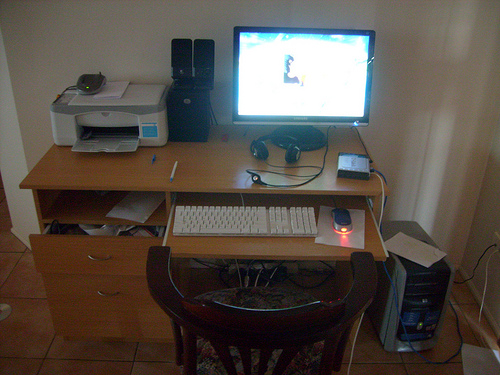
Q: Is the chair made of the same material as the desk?
A: Yes, both the chair and the desk are made of wood.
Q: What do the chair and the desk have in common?
A: The material, both the chair and the desk are wooden.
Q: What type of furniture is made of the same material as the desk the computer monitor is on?
A: The chair is made of the same material as the desk.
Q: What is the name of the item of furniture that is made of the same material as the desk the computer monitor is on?
A: The piece of furniture is a chair.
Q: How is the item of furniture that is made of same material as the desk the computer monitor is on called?
A: The piece of furniture is a chair.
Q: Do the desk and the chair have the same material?
A: Yes, both the desk and the chair are made of wood.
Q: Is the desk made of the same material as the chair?
A: Yes, both the desk and the chair are made of wood.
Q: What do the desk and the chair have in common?
A: The material, both the desk and the chair are wooden.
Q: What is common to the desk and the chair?
A: The material, both the desk and the chair are wooden.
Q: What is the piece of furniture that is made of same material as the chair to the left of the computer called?
A: The piece of furniture is a desk.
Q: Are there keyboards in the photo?
A: Yes, there is a keyboard.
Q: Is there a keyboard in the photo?
A: Yes, there is a keyboard.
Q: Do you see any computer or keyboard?
A: Yes, there is a keyboard.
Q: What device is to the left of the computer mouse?
A: The device is a keyboard.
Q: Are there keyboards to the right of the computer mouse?
A: No, the keyboard is to the left of the computer mouse.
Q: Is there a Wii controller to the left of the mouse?
A: No, there is a keyboard to the left of the mouse.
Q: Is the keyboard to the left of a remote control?
A: No, the keyboard is to the left of the computer mouse.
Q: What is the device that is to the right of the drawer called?
A: The device is a keyboard.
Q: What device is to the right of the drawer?
A: The device is a keyboard.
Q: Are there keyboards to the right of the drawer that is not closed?
A: Yes, there is a keyboard to the right of the drawer.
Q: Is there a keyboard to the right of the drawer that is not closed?
A: Yes, there is a keyboard to the right of the drawer.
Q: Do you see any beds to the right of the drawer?
A: No, there is a keyboard to the right of the drawer.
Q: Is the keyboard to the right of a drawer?
A: Yes, the keyboard is to the right of a drawer.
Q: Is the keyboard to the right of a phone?
A: No, the keyboard is to the right of a drawer.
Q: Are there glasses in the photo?
A: No, there are no glasses.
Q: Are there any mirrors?
A: No, there are no mirrors.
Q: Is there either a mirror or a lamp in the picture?
A: No, there are no mirrors or lamps.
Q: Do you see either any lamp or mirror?
A: No, there are no mirrors or lamps.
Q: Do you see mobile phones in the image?
A: No, there are no mobile phones.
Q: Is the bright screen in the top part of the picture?
A: Yes, the screen is in the top of the image.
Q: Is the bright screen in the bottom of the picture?
A: No, the screen is in the top of the image.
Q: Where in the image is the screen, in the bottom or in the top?
A: The screen is in the top of the image.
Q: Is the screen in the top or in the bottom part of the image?
A: The screen is in the top of the image.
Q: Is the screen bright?
A: Yes, the screen is bright.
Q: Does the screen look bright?
A: Yes, the screen is bright.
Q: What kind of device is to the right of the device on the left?
A: The device is a screen.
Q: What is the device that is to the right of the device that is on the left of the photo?
A: The device is a screen.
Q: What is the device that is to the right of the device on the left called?
A: The device is a screen.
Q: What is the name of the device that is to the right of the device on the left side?
A: The device is a screen.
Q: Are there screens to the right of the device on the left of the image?
A: Yes, there is a screen to the right of the printer.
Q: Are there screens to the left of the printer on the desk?
A: No, the screen is to the right of the printer.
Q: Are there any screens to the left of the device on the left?
A: No, the screen is to the right of the printer.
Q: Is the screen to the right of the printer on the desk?
A: Yes, the screen is to the right of the printer.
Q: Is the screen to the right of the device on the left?
A: Yes, the screen is to the right of the printer.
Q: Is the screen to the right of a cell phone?
A: No, the screen is to the right of the printer.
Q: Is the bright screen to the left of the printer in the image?
A: No, the screen is to the right of the printer.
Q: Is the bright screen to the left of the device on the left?
A: No, the screen is to the right of the printer.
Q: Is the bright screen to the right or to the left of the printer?
A: The screen is to the right of the printer.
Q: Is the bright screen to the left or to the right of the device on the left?
A: The screen is to the right of the printer.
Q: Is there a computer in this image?
A: Yes, there is a computer.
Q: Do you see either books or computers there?
A: Yes, there is a computer.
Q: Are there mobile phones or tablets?
A: No, there are no mobile phones or tablets.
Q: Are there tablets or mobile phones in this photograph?
A: No, there are no mobile phones or tablets.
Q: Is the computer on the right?
A: Yes, the computer is on the right of the image.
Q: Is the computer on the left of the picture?
A: No, the computer is on the right of the image.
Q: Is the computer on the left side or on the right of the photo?
A: The computer is on the right of the image.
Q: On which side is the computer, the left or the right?
A: The computer is on the right of the image.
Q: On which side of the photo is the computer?
A: The computer is on the right of the image.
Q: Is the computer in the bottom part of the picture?
A: Yes, the computer is in the bottom of the image.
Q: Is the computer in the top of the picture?
A: No, the computer is in the bottom of the image.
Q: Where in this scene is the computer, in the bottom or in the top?
A: The computer is in the bottom of the image.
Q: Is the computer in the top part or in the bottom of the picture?
A: The computer is in the bottom of the image.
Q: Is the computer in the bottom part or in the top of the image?
A: The computer is in the bottom of the image.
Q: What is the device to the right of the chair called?
A: The device is a computer.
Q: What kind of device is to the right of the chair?
A: The device is a computer.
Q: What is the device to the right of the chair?
A: The device is a computer.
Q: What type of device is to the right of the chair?
A: The device is a computer.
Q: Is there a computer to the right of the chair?
A: Yes, there is a computer to the right of the chair.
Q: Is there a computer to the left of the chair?
A: No, the computer is to the right of the chair.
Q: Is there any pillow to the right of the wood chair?
A: No, there is a computer to the right of the chair.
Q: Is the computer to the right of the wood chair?
A: Yes, the computer is to the right of the chair.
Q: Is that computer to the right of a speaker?
A: No, the computer is to the right of the chair.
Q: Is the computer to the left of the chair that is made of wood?
A: No, the computer is to the right of the chair.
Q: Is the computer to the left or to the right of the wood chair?
A: The computer is to the right of the chair.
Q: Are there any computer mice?
A: Yes, there is a computer mouse.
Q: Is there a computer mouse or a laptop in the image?
A: Yes, there is a computer mouse.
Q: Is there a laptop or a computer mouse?
A: Yes, there is a computer mouse.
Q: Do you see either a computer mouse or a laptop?
A: Yes, there is a computer mouse.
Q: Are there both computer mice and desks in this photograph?
A: Yes, there are both a computer mouse and a desk.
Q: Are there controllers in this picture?
A: No, there are no controllers.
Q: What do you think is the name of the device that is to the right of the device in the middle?
A: The device is a computer mouse.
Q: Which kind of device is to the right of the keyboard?
A: The device is a computer mouse.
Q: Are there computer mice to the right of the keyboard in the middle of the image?
A: Yes, there is a computer mouse to the right of the keyboard.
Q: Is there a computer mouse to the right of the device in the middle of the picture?
A: Yes, there is a computer mouse to the right of the keyboard.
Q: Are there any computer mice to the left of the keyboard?
A: No, the computer mouse is to the right of the keyboard.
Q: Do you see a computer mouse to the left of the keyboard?
A: No, the computer mouse is to the right of the keyboard.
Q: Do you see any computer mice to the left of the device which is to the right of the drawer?
A: No, the computer mouse is to the right of the keyboard.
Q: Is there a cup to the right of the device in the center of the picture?
A: No, there is a computer mouse to the right of the keyboard.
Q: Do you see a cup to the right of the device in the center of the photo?
A: No, there is a computer mouse to the right of the keyboard.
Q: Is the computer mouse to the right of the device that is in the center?
A: Yes, the computer mouse is to the right of the keyboard.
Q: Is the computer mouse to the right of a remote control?
A: No, the computer mouse is to the right of the keyboard.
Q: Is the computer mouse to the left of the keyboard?
A: No, the computer mouse is to the right of the keyboard.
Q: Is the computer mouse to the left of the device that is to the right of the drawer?
A: No, the computer mouse is to the right of the keyboard.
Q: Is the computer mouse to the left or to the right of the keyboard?
A: The computer mouse is to the right of the keyboard.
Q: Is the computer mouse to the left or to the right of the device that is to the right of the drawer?
A: The computer mouse is to the right of the keyboard.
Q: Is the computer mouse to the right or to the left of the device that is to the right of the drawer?
A: The computer mouse is to the right of the keyboard.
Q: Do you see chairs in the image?
A: Yes, there is a chair.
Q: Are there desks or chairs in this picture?
A: Yes, there is a chair.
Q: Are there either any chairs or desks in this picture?
A: Yes, there is a chair.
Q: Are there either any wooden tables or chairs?
A: Yes, there is a wood chair.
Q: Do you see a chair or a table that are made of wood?
A: Yes, the chair is made of wood.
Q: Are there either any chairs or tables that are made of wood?
A: Yes, the chair is made of wood.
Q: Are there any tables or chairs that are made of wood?
A: Yes, the chair is made of wood.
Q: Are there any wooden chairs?
A: Yes, there is a wood chair.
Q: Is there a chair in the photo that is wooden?
A: Yes, there is a chair that is wooden.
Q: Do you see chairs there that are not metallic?
A: Yes, there is a wooden chair.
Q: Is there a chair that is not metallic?
A: Yes, there is a wooden chair.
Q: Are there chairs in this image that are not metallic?
A: Yes, there is a wooden chair.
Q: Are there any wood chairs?
A: Yes, there is a chair that is made of wood.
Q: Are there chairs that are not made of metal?
A: Yes, there is a chair that is made of wood.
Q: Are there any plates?
A: No, there are no plates.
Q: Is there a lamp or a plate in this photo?
A: No, there are no plates or lamps.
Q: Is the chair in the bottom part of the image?
A: Yes, the chair is in the bottom of the image.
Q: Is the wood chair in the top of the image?
A: No, the chair is in the bottom of the image.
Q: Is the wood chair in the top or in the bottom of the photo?
A: The chair is in the bottom of the image.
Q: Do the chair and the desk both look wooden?
A: Yes, both the chair and the desk are wooden.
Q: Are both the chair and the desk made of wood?
A: Yes, both the chair and the desk are made of wood.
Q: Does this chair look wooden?
A: Yes, the chair is wooden.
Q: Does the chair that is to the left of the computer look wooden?
A: Yes, the chair is wooden.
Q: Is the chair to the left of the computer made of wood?
A: Yes, the chair is made of wood.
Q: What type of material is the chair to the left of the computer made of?
A: The chair is made of wood.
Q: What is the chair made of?
A: The chair is made of wood.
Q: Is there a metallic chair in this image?
A: No, there is a chair but it is wooden.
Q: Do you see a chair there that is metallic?
A: No, there is a chair but it is wooden.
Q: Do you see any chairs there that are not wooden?
A: No, there is a chair but it is wooden.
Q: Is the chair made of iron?
A: No, the chair is made of wood.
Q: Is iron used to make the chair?
A: No, the chair is made of wood.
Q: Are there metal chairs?
A: No, there is a chair but it is made of wood.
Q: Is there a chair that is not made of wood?
A: No, there is a chair but it is made of wood.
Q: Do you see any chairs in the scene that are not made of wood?
A: No, there is a chair but it is made of wood.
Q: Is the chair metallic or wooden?
A: The chair is wooden.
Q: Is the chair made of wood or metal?
A: The chair is made of wood.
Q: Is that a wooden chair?
A: Yes, that is a wooden chair.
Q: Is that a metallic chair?
A: No, that is a wooden chair.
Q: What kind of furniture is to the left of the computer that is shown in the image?
A: The piece of furniture is a chair.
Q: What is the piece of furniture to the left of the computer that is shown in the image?
A: The piece of furniture is a chair.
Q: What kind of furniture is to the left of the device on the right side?
A: The piece of furniture is a chair.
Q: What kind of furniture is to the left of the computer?
A: The piece of furniture is a chair.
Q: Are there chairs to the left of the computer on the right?
A: Yes, there is a chair to the left of the computer.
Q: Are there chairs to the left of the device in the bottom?
A: Yes, there is a chair to the left of the computer.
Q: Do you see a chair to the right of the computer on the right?
A: No, the chair is to the left of the computer.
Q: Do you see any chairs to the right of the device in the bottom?
A: No, the chair is to the left of the computer.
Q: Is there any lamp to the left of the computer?
A: No, there is a chair to the left of the computer.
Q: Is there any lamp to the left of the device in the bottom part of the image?
A: No, there is a chair to the left of the computer.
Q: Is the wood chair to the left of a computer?
A: Yes, the chair is to the left of a computer.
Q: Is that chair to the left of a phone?
A: No, the chair is to the left of a computer.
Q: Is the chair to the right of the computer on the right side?
A: No, the chair is to the left of the computer.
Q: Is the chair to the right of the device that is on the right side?
A: No, the chair is to the left of the computer.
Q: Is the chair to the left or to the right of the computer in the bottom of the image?
A: The chair is to the left of the computer.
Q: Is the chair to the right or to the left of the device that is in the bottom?
A: The chair is to the left of the computer.